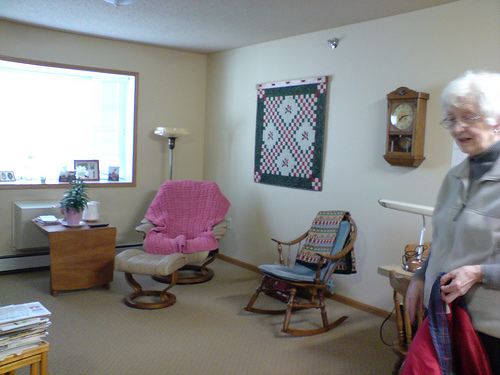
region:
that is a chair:
[132, 178, 207, 301]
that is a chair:
[253, 204, 355, 326]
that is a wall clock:
[382, 80, 427, 167]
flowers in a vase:
[52, 186, 83, 231]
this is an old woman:
[415, 77, 497, 342]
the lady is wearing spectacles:
[422, 109, 494, 134]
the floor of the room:
[139, 318, 219, 348]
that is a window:
[0, 75, 140, 180]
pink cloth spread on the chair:
[144, 180, 216, 259]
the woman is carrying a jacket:
[412, 270, 475, 372]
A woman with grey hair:
[423, 71, 498, 367]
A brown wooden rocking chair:
[252, 195, 367, 336]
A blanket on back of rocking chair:
[296, 206, 356, 267]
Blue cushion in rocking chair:
[263, 265, 330, 280]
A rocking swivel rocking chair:
[118, 195, 230, 309]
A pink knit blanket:
[143, 180, 228, 257]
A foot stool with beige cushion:
[115, 240, 197, 317]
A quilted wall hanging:
[248, 76, 359, 196]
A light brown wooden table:
[36, 217, 116, 297]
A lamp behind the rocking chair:
[151, 109, 205, 189]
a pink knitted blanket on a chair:
[144, 178, 229, 253]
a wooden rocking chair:
[247, 210, 359, 340]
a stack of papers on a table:
[1, 298, 51, 363]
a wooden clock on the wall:
[384, 85, 430, 166]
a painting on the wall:
[254, 75, 328, 192]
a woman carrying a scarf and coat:
[395, 263, 493, 373]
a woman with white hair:
[435, 69, 499, 157]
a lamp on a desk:
[379, 197, 432, 270]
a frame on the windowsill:
[72, 157, 101, 182]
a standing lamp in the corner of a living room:
[156, 127, 187, 179]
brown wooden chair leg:
[281, 288, 299, 332]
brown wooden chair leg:
[313, 289, 329, 324]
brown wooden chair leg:
[247, 275, 269, 311]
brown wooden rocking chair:
[244, 210, 359, 339]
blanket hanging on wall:
[248, 77, 327, 199]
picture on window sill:
[105, 164, 124, 181]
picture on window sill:
[73, 156, 103, 181]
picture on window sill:
[0, 170, 17, 182]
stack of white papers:
[1, 299, 56, 361]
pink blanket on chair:
[143, 178, 232, 252]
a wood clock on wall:
[386, 87, 429, 165]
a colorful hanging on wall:
[257, 78, 325, 189]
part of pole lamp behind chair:
[162, 123, 184, 174]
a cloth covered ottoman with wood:
[119, 248, 176, 310]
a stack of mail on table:
[1, 303, 53, 366]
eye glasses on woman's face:
[438, 118, 479, 126]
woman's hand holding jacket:
[406, 269, 495, 370]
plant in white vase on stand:
[58, 186, 93, 228]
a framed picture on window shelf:
[1, 169, 18, 180]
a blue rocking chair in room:
[243, 205, 359, 336]